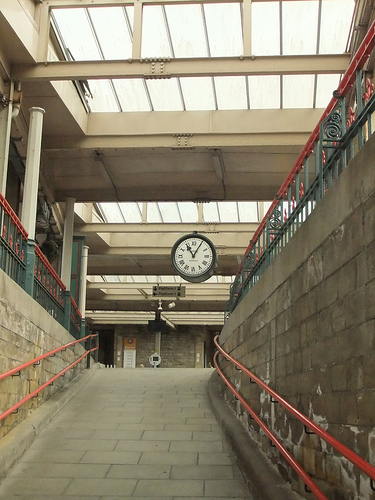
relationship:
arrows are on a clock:
[193, 238, 202, 259] [169, 232, 218, 283]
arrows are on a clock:
[186, 241, 194, 259] [169, 232, 218, 283]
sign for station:
[122, 333, 136, 367] [0, 0, 374, 499]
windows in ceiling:
[51, 0, 365, 116] [1, 0, 374, 327]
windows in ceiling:
[74, 200, 316, 225] [1, 0, 374, 327]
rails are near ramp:
[208, 336, 373, 499] [0, 365, 265, 499]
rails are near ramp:
[0, 332, 102, 419] [0, 365, 265, 499]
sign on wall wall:
[122, 333, 136, 367] [112, 325, 213, 366]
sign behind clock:
[122, 333, 136, 367] [169, 232, 218, 283]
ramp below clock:
[0, 365, 265, 499] [169, 232, 218, 283]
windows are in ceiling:
[51, 0, 365, 116] [1, 0, 374, 327]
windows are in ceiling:
[74, 200, 316, 225] [1, 0, 374, 327]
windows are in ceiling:
[87, 274, 235, 285] [1, 0, 374, 327]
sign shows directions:
[154, 285, 186, 295] [152, 285, 156, 297]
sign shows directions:
[154, 285, 186, 295] [176, 285, 182, 297]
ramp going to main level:
[0, 365, 265, 499] [5, 81, 374, 368]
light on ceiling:
[95, 155, 118, 194] [1, 0, 374, 327]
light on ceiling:
[209, 155, 224, 192] [1, 0, 374, 327]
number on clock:
[192, 238, 198, 247] [169, 232, 218, 283]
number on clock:
[202, 247, 208, 253] [169, 232, 218, 283]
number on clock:
[203, 252, 211, 260] [169, 232, 218, 283]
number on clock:
[201, 260, 208, 266] [169, 232, 218, 283]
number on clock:
[191, 265, 197, 272] [169, 232, 218, 283]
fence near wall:
[1, 197, 99, 353] [2, 268, 101, 483]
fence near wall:
[221, 25, 373, 317] [216, 132, 373, 499]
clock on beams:
[169, 232, 218, 283] [73, 221, 269, 232]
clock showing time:
[169, 232, 218, 283] [185, 237, 206, 258]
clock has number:
[169, 232, 218, 283] [192, 238, 198, 247]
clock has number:
[169, 232, 218, 283] [203, 252, 211, 260]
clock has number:
[169, 232, 218, 283] [201, 260, 208, 266]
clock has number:
[169, 232, 218, 283] [191, 265, 197, 272]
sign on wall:
[122, 333, 136, 367] [112, 325, 213, 366]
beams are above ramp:
[13, 54, 374, 87] [0, 365, 265, 499]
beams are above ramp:
[73, 221, 269, 232] [0, 365, 265, 499]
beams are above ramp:
[84, 311, 226, 321] [0, 365, 265, 499]